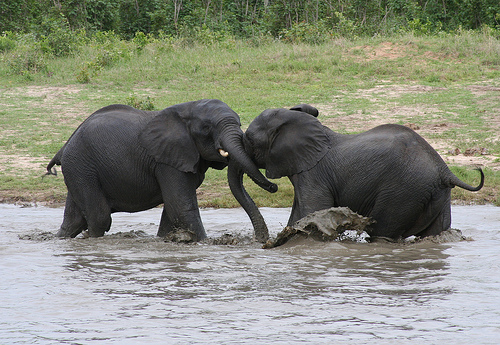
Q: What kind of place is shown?
A: It is a lake.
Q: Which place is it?
A: It is a lake.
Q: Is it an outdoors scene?
A: Yes, it is outdoors.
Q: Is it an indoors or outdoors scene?
A: It is outdoors.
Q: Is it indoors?
A: No, it is outdoors.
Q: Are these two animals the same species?
A: Yes, all the animals are elephants.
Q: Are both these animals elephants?
A: Yes, all the animals are elephants.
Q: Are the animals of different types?
A: No, all the animals are elephants.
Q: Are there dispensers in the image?
A: No, there are no dispensers.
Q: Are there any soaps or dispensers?
A: No, there are no dispensers or soaps.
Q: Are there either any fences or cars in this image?
A: No, there are no fences or cars.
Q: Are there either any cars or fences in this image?
A: No, there are no fences or cars.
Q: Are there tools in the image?
A: No, there are no tools.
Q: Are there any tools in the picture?
A: No, there are no tools.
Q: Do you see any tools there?
A: No, there are no tools.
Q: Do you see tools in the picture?
A: No, there are no tools.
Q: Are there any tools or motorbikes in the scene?
A: No, there are no tools or motorbikes.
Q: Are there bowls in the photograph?
A: No, there are no bowls.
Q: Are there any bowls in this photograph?
A: No, there are no bowls.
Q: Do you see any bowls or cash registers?
A: No, there are no bowls or cash registers.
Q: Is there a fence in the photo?
A: No, there are no fences.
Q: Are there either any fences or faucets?
A: No, there are no fences or faucets.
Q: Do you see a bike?
A: No, there are no bikes.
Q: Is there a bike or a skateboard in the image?
A: No, there are no bikes or skateboards.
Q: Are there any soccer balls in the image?
A: No, there are no soccer balls.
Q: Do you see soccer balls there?
A: No, there are no soccer balls.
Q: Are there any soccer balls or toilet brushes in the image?
A: No, there are no soccer balls or toilet brushes.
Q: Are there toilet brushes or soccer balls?
A: No, there are no soccer balls or toilet brushes.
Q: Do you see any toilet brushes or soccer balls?
A: No, there are no soccer balls or toilet brushes.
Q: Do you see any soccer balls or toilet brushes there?
A: No, there are no soccer balls or toilet brushes.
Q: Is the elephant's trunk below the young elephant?
A: Yes, the trunk is below the elephant.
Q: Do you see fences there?
A: No, there are no fences.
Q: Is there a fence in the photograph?
A: No, there are no fences.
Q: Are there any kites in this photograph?
A: No, there are no kites.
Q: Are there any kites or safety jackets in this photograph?
A: No, there are no kites or safety jackets.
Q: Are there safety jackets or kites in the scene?
A: No, there are no kites or safety jackets.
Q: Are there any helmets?
A: No, there are no helmets.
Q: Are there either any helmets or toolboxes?
A: No, there are no helmets or toolboxes.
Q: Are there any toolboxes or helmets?
A: No, there are no helmets or toolboxes.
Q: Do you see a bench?
A: No, there are no benches.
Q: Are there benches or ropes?
A: No, there are no benches or ropes.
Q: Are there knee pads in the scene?
A: No, there are no knee pads.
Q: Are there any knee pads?
A: No, there are no knee pads.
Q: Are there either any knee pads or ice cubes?
A: No, there are no knee pads or ice cubes.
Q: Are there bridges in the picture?
A: No, there are no bridges.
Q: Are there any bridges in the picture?
A: No, there are no bridges.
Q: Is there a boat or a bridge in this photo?
A: No, there are no bridges or boats.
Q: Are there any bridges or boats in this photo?
A: No, there are no bridges or boats.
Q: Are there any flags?
A: No, there are no flags.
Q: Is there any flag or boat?
A: No, there are no flags or boats.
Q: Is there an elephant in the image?
A: Yes, there is an elephant.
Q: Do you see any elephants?
A: Yes, there is an elephant.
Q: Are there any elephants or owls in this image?
A: Yes, there is an elephant.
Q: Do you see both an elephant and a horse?
A: No, there is an elephant but no horses.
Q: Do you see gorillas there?
A: No, there are no gorillas.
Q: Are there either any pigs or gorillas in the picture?
A: No, there are no gorillas or pigs.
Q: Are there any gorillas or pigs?
A: No, there are no gorillas or pigs.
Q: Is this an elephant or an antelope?
A: This is an elephant.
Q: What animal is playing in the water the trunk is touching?
A: The elephant is playing in the water.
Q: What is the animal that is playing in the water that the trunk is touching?
A: The animal is an elephant.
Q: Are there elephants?
A: Yes, there is an elephant.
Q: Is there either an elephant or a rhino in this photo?
A: Yes, there is an elephant.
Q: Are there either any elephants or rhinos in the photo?
A: Yes, there is an elephant.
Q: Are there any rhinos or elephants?
A: Yes, there is an elephant.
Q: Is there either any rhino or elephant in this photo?
A: Yes, there is an elephant.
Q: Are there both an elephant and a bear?
A: No, there is an elephant but no bears.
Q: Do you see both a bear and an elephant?
A: No, there is an elephant but no bears.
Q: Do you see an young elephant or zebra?
A: Yes, there is a young elephant.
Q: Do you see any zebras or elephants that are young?
A: Yes, the elephant is young.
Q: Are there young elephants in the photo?
A: Yes, there is a young elephant.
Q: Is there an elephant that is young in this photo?
A: Yes, there is a young elephant.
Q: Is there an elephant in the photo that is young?
A: Yes, there is an elephant that is young.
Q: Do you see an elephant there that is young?
A: Yes, there is an elephant that is young.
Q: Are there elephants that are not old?
A: Yes, there is an young elephant.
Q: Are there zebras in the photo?
A: No, there are no zebras.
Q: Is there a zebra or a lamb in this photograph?
A: No, there are no zebras or lambs.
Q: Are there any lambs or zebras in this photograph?
A: No, there are no zebras or lambs.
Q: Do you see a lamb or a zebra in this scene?
A: No, there are no zebras or lambs.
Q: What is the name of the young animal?
A: The animal is an elephant.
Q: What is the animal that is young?
A: The animal is an elephant.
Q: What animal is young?
A: The animal is an elephant.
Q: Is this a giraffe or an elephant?
A: This is an elephant.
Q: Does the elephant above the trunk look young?
A: Yes, the elephant is young.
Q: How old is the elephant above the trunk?
A: The elephant is young.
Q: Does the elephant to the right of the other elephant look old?
A: No, the elephant is young.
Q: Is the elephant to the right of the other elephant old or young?
A: The elephant is young.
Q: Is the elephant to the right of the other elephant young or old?
A: The elephant is young.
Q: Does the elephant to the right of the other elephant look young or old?
A: The elephant is young.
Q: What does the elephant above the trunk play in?
A: The elephant plays in the water.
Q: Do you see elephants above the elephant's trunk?
A: Yes, there is an elephant above the trunk.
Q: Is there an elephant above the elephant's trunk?
A: Yes, there is an elephant above the trunk.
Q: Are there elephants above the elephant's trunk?
A: Yes, there is an elephant above the trunk.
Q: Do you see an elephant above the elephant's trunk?
A: Yes, there is an elephant above the trunk.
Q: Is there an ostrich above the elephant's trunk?
A: No, there is an elephant above the trunk.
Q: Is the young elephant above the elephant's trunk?
A: Yes, the elephant is above the trunk.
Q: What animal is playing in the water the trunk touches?
A: The elephant is playing in the water.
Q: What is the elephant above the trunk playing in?
A: The elephant is playing in the water.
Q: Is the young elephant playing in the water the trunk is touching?
A: Yes, the elephant is playing in the water.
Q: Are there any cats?
A: No, there are no cats.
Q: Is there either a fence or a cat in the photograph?
A: No, there are no cats or fences.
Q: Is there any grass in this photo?
A: Yes, there is grass.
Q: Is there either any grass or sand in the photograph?
A: Yes, there is grass.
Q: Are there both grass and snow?
A: No, there is grass but no snow.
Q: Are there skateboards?
A: No, there are no skateboards.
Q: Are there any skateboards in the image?
A: No, there are no skateboards.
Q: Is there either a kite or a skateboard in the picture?
A: No, there are no skateboards or kites.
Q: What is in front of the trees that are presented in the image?
A: The grass is in front of the trees.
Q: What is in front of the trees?
A: The grass is in front of the trees.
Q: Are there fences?
A: No, there are no fences.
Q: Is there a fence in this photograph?
A: No, there are no fences.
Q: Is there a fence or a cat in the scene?
A: No, there are no fences or cats.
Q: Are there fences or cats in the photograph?
A: No, there are no fences or cats.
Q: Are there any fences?
A: No, there are no fences.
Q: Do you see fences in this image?
A: No, there are no fences.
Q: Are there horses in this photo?
A: No, there are no horses.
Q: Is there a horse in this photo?
A: No, there are no horses.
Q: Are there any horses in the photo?
A: No, there are no horses.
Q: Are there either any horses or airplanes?
A: No, there are no horses or airplanes.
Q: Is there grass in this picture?
A: Yes, there is grass.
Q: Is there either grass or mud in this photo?
A: Yes, there is grass.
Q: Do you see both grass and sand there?
A: No, there is grass but no sand.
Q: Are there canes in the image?
A: No, there are no canes.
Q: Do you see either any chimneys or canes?
A: No, there are no canes or chimneys.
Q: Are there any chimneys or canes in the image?
A: No, there are no canes or chimneys.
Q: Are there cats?
A: No, there are no cats.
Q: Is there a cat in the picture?
A: No, there are no cats.